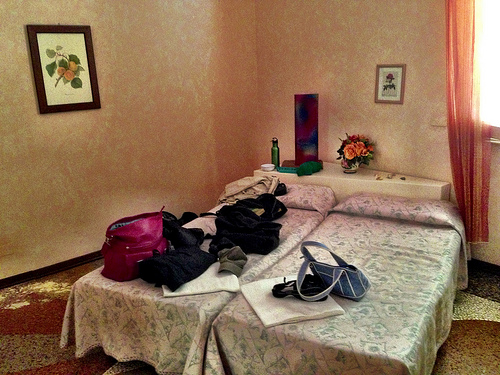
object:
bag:
[98, 206, 165, 283]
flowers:
[42, 44, 86, 90]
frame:
[80, 29, 103, 111]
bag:
[290, 237, 374, 303]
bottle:
[268, 135, 282, 170]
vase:
[335, 131, 376, 174]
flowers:
[343, 141, 370, 160]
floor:
[0, 273, 59, 375]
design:
[451, 276, 499, 330]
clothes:
[160, 213, 241, 299]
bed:
[200, 190, 469, 373]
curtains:
[443, 0, 493, 245]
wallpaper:
[129, 43, 210, 132]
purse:
[268, 230, 373, 304]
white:
[344, 271, 356, 299]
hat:
[296, 161, 324, 177]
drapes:
[451, 153, 495, 243]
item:
[275, 166, 298, 174]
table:
[253, 157, 451, 201]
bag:
[204, 217, 286, 259]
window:
[469, 0, 500, 127]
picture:
[376, 66, 402, 102]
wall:
[253, 3, 370, 92]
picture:
[37, 19, 94, 105]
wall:
[0, 115, 256, 166]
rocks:
[399, 176, 409, 183]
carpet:
[432, 257, 499, 373]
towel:
[238, 273, 346, 329]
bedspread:
[201, 213, 456, 374]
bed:
[57, 177, 336, 374]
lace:
[464, 239, 490, 247]